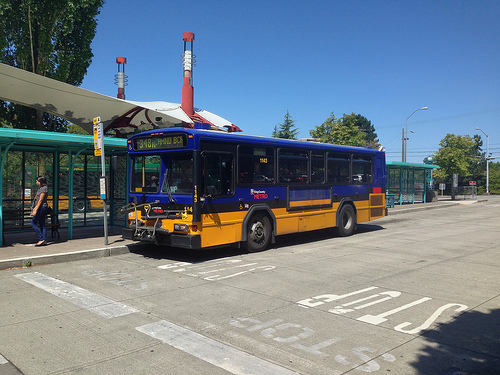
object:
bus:
[120, 126, 391, 255]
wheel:
[241, 213, 273, 253]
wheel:
[337, 204, 358, 238]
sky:
[231, 12, 275, 35]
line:
[11, 269, 142, 319]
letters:
[327, 289, 402, 315]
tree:
[0, 0, 105, 91]